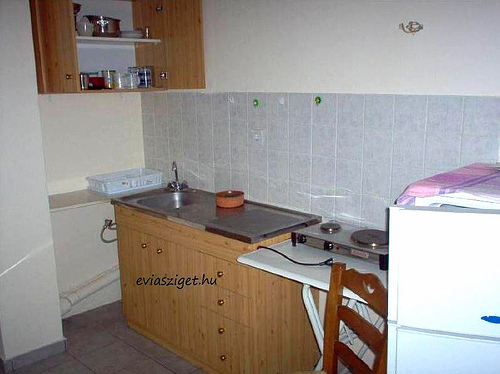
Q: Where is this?
A: This is at the kitchen.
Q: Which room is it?
A: It is a kitchen.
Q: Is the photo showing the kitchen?
A: Yes, it is showing the kitchen.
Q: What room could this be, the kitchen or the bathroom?
A: It is the kitchen.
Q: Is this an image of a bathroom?
A: No, the picture is showing a kitchen.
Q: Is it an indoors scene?
A: Yes, it is indoors.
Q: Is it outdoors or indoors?
A: It is indoors.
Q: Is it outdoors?
A: No, it is indoors.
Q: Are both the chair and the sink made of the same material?
A: No, the chair is made of wood and the sink is made of metal.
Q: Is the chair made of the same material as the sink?
A: No, the chair is made of wood and the sink is made of metal.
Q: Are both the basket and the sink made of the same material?
A: No, the basket is made of plastic and the sink is made of metal.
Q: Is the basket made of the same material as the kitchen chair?
A: No, the basket is made of plastic and the chair is made of wood.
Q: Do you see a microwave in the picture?
A: No, there are no microwaves.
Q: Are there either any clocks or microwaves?
A: No, there are no microwaves or clocks.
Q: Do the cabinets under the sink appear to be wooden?
A: Yes, the cabinets are wooden.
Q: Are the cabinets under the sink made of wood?
A: Yes, the cabinets are made of wood.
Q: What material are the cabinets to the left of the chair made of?
A: The cabinets are made of wood.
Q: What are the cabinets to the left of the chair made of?
A: The cabinets are made of wood.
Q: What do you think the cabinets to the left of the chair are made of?
A: The cabinets are made of wood.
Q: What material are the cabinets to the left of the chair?
A: The cabinets are made of wood.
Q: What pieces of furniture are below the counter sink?
A: The pieces of furniture are cabinets.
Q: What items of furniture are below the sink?
A: The pieces of furniture are cabinets.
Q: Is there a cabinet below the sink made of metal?
A: Yes, there are cabinets below the sink.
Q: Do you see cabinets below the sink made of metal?
A: Yes, there are cabinets below the sink.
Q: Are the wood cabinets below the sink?
A: Yes, the cabinets are below the sink.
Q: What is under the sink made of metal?
A: The cabinets are under the sink.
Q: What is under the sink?
A: The cabinets are under the sink.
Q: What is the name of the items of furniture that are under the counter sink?
A: The pieces of furniture are cabinets.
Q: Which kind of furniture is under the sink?
A: The pieces of furniture are cabinets.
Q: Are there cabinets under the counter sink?
A: Yes, there are cabinets under the sink.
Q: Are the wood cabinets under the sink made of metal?
A: Yes, the cabinets are under the sink.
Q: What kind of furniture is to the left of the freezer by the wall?
A: The pieces of furniture are cabinets.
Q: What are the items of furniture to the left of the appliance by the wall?
A: The pieces of furniture are cabinets.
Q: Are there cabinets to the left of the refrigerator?
A: Yes, there are cabinets to the left of the refrigerator.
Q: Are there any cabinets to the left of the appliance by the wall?
A: Yes, there are cabinets to the left of the refrigerator.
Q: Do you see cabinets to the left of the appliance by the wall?
A: Yes, there are cabinets to the left of the refrigerator.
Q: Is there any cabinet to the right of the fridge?
A: No, the cabinets are to the left of the fridge.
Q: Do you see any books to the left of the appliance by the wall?
A: No, there are cabinets to the left of the fridge.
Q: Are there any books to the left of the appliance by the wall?
A: No, there are cabinets to the left of the fridge.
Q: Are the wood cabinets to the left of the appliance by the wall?
A: Yes, the cabinets are to the left of the fridge.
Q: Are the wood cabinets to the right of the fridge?
A: No, the cabinets are to the left of the fridge.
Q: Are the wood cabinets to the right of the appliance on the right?
A: No, the cabinets are to the left of the fridge.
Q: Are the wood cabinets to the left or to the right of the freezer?
A: The cabinets are to the left of the freezer.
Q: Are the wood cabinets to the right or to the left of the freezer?
A: The cabinets are to the left of the freezer.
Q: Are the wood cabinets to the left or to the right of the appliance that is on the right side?
A: The cabinets are to the left of the freezer.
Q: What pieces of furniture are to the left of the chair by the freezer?
A: The pieces of furniture are cabinets.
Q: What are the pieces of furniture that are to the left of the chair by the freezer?
A: The pieces of furniture are cabinets.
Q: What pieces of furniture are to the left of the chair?
A: The pieces of furniture are cabinets.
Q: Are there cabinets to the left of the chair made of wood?
A: Yes, there are cabinets to the left of the chair.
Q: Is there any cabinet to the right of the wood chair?
A: No, the cabinets are to the left of the chair.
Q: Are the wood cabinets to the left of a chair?
A: Yes, the cabinets are to the left of a chair.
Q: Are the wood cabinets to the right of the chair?
A: No, the cabinets are to the left of the chair.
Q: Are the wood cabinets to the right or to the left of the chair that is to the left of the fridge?
A: The cabinets are to the left of the chair.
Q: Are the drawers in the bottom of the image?
A: Yes, the drawers are in the bottom of the image.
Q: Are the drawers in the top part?
A: No, the drawers are in the bottom of the image.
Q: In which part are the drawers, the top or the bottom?
A: The drawers are in the bottom of the image.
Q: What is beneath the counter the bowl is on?
A: The drawers are beneath the counter.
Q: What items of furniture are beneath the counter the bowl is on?
A: The pieces of furniture are drawers.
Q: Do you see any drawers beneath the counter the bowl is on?
A: Yes, there are drawers beneath the counter.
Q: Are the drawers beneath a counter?
A: Yes, the drawers are beneath a counter.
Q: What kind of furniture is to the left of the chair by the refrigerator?
A: The pieces of furniture are drawers.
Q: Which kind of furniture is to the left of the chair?
A: The pieces of furniture are drawers.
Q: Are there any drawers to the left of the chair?
A: Yes, there are drawers to the left of the chair.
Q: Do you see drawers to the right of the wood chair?
A: No, the drawers are to the left of the chair.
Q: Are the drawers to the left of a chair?
A: Yes, the drawers are to the left of a chair.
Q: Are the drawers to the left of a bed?
A: No, the drawers are to the left of a chair.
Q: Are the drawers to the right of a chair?
A: No, the drawers are to the left of a chair.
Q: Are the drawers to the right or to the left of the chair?
A: The drawers are to the left of the chair.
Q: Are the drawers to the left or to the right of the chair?
A: The drawers are to the left of the chair.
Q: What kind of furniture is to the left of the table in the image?
A: The pieces of furniture are drawers.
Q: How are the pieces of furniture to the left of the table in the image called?
A: The pieces of furniture are drawers.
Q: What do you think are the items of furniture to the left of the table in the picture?
A: The pieces of furniture are drawers.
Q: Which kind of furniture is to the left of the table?
A: The pieces of furniture are drawers.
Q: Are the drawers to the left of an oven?
A: No, the drawers are to the left of the table.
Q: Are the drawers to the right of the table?
A: No, the drawers are to the left of the table.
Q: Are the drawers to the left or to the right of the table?
A: The drawers are to the left of the table.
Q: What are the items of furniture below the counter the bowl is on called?
A: The pieces of furniture are drawers.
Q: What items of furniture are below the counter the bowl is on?
A: The pieces of furniture are drawers.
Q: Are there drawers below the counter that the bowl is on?
A: Yes, there are drawers below the counter.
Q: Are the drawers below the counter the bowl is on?
A: Yes, the drawers are below the counter.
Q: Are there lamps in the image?
A: No, there are no lamps.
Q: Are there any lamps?
A: No, there are no lamps.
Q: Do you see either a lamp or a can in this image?
A: No, there are no lamps or cans.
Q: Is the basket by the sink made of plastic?
A: Yes, the basket is made of plastic.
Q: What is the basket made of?
A: The basket is made of plastic.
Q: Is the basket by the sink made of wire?
A: No, the basket is made of plastic.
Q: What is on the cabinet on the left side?
A: The basket is on the cabinet.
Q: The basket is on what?
A: The basket is on the cabinet.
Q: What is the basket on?
A: The basket is on the cabinet.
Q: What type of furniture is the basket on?
A: The basket is on the cabinet.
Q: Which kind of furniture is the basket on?
A: The basket is on the cabinet.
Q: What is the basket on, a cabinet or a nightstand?
A: The basket is on a cabinet.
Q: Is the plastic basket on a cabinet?
A: Yes, the basket is on a cabinet.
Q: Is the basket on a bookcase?
A: No, the basket is on a cabinet.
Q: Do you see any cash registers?
A: No, there are no cash registers.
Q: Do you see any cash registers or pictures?
A: No, there are no cash registers or pictures.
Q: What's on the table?
A: The burner is on the table.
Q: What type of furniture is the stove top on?
A: The stove top is on the table.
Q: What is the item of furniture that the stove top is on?
A: The piece of furniture is a table.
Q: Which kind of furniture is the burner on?
A: The stove top is on the table.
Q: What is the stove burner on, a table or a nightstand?
A: The stove burner is on a table.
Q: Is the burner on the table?
A: Yes, the burner is on the table.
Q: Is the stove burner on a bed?
A: No, the stove burner is on the table.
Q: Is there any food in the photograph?
A: No, there is no food.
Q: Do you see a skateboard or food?
A: No, there are no food or skateboards.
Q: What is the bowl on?
A: The bowl is on the counter.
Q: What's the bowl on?
A: The bowl is on the counter.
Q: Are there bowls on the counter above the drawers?
A: Yes, there is a bowl on the counter.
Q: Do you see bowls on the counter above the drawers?
A: Yes, there is a bowl on the counter.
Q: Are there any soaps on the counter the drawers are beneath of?
A: No, there is a bowl on the counter.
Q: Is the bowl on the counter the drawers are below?
A: Yes, the bowl is on the counter.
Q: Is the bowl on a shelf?
A: No, the bowl is on the counter.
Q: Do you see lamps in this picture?
A: No, there are no lamps.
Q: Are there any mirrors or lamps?
A: No, there are no lamps or mirrors.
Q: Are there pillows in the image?
A: No, there are no pillows.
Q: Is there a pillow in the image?
A: No, there are no pillows.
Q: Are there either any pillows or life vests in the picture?
A: No, there are no pillows or life vests.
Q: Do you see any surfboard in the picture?
A: No, there are no surfboards.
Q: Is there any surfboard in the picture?
A: No, there are no surfboards.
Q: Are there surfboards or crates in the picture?
A: No, there are no surfboards or crates.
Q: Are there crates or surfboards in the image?
A: No, there are no surfboards or crates.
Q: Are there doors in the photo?
A: Yes, there is a door.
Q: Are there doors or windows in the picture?
A: Yes, there is a door.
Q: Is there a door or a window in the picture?
A: Yes, there is a door.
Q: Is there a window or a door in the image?
A: Yes, there is a door.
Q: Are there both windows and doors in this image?
A: No, there is a door but no windows.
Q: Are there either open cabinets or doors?
A: Yes, there is an open door.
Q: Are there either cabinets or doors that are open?
A: Yes, the door is open.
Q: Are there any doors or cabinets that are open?
A: Yes, the door is open.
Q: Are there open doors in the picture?
A: Yes, there is an open door.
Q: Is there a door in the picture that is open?
A: Yes, there is a door that is open.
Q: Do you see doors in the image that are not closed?
A: Yes, there is a open door.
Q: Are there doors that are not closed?
A: Yes, there is a open door.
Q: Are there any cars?
A: No, there are no cars.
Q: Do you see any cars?
A: No, there are no cars.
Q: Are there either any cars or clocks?
A: No, there are no cars or clocks.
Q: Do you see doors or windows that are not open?
A: No, there is a door but it is open.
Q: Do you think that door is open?
A: Yes, the door is open.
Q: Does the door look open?
A: Yes, the door is open.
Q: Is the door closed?
A: No, the door is open.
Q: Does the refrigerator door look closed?
A: No, the door is open.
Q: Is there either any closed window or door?
A: No, there is a door but it is open.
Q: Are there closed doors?
A: No, there is a door but it is open.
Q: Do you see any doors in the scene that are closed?
A: No, there is a door but it is open.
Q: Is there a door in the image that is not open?
A: No, there is a door but it is open.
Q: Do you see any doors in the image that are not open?
A: No, there is a door but it is open.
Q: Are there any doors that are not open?
A: No, there is a door but it is open.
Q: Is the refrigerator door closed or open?
A: The door is open.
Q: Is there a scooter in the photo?
A: No, there are no scooters.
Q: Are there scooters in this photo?
A: No, there are no scooters.